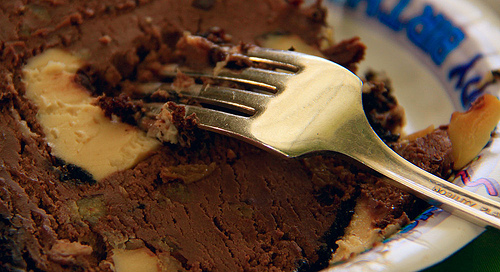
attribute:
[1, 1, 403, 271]
ice cream — chocolate, part eaten, brown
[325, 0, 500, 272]
bowl — paper, white, blue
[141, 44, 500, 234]
fork — silver, face down, upside down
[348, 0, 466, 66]
writing — blue